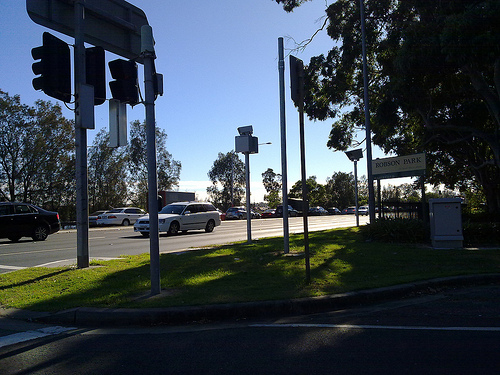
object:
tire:
[29, 222, 48, 240]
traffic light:
[29, 32, 70, 103]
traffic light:
[108, 59, 138, 106]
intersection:
[0, 288, 75, 357]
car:
[134, 200, 221, 237]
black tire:
[122, 218, 129, 226]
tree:
[277, 0, 500, 195]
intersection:
[1, 239, 36, 311]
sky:
[0, 0, 402, 188]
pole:
[357, 1, 377, 227]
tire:
[168, 221, 180, 236]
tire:
[122, 218, 130, 226]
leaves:
[312, 36, 369, 121]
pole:
[144, 52, 162, 294]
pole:
[74, 32, 94, 266]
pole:
[274, 37, 292, 252]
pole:
[296, 103, 312, 279]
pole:
[354, 23, 381, 224]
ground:
[422, 199, 470, 251]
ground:
[403, 141, 439, 173]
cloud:
[123, 179, 327, 200]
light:
[28, 31, 71, 104]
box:
[429, 197, 464, 249]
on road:
[8, 177, 159, 282]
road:
[12, 303, 493, 368]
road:
[25, 173, 254, 265]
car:
[0, 202, 60, 242]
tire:
[205, 219, 215, 232]